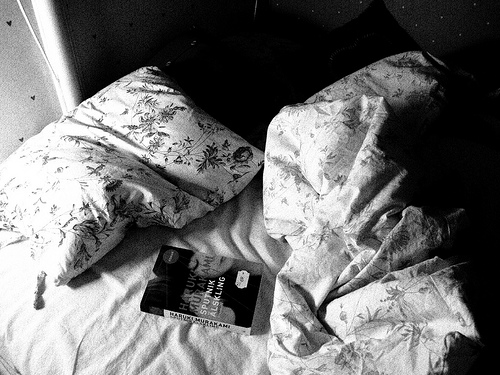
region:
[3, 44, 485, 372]
this is a bed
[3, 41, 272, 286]
pillow on the bed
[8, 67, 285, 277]
floral print on the pillow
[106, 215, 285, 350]
this is a book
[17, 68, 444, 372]
book on the bed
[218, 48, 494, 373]
this is a comforter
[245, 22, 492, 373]
floral prints on comforter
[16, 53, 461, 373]
the bed is not made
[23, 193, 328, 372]
solid sheet on bed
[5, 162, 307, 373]
fitted sheet is wrinkled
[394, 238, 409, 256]
part of a cloth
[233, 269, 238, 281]
part of a book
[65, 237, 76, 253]
part of a pillow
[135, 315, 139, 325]
edge of a bed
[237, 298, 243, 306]
side of a book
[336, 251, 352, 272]
part of a blanket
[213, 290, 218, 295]
edge of a book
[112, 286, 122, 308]
side of a bed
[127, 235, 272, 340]
this is a book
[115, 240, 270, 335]
a paperback book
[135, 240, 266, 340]
a book written by Murakami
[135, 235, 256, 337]
a book written by Haruki Murakami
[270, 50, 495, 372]
this is a comforter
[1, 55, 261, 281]
this is a pillow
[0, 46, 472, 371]
the pillowcase and comforter match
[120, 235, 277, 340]
the book is on a bed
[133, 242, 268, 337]
a paperback on a bed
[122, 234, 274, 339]
a novel on a bed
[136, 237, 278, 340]
book laying on bed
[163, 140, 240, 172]
floral design on pillow cover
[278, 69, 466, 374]
sheet laying on bed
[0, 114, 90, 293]
sunlight shining on pillow cover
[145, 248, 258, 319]
image on front of book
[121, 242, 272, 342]
closed book laying on bed sheet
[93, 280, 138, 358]
wrinkles in white bed sheet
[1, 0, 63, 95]
white string on window blindes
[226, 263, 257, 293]
small white design on book cover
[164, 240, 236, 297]
woman on cover of book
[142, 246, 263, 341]
a paperback book lays in the bed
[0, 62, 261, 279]
a floral print pillowcase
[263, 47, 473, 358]
the top flat sheet has a floral print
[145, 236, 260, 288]
a young woman closes her eyes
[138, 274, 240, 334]
the profile of a young man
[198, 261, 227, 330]
A book written in Swedish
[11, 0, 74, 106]
a cord for a window blind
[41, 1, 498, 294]
a bed made on a window sill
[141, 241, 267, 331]
a romance novel translated from Japanese